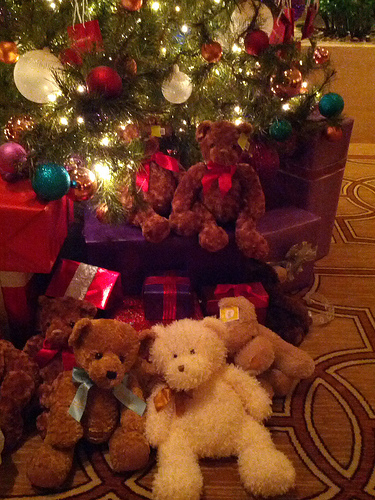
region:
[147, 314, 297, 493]
fuzzy white teddy bear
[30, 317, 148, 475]
soft brown teddy bear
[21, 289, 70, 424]
soft brown teddy with red ribbon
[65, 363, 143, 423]
light blue ribbon on teddy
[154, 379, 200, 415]
brown satin ribbon on teddy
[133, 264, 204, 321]
purple present with red ribbon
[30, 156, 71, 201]
sparkly teal ornament on tree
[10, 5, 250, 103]
decorated and lit up christmas tree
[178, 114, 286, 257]
teddy bear with a red ribbon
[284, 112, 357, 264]
tall purple present with purple ribbon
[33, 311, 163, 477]
Dark brown bear in a pile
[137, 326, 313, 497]
Light brown bear in a pile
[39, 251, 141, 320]
Box under a tree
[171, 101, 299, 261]
Brown bear on a chair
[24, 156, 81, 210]
Blue christmas ornament on a tree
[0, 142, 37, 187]
Purple ornament on a tree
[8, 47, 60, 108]
Large white ornament on a tree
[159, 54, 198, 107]
Small glass ornament on a tree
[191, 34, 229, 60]
Small red ornament on a tree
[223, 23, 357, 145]
Ornaments on a christmas tree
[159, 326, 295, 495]
White teddy bear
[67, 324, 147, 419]
Brown teddy bear with blue ribbon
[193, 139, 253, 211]
brown teddy bear with red ribbon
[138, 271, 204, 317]
Purple box with pink lace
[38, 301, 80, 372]
Brown teddy bear with red ribbon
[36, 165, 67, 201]
green ornament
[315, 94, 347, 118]
Green ornament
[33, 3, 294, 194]
Christmas tree with ornaments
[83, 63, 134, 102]
red ornament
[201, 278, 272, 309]
Pink box with bow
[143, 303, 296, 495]
the teddy bear is white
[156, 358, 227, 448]
the teddy bear is white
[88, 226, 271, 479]
the teddy bear is white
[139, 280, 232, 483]
the teddy bear is white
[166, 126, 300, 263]
teddy bear with red bow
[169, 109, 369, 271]
teddy bear sitting on chair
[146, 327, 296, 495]
white teddy bear with ribbon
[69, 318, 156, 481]
blue ribbon on brown teddy bear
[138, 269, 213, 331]
purple wrapping with red ribbon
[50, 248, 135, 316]
red wrapping paper and silver trim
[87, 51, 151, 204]
white lights on Christmas tree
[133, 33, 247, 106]
ornaments hanging on tree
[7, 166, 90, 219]
green ornament on table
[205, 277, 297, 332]
red gift box with bow